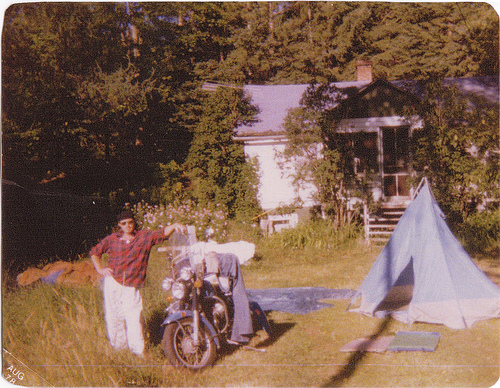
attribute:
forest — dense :
[5, 1, 498, 259]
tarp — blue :
[247, 282, 361, 315]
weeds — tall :
[33, 308, 100, 370]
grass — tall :
[19, 283, 122, 376]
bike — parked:
[153, 248, 223, 366]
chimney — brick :
[353, 54, 381, 74]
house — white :
[169, 64, 496, 305]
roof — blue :
[234, 72, 409, 140]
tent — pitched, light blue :
[355, 173, 498, 326]